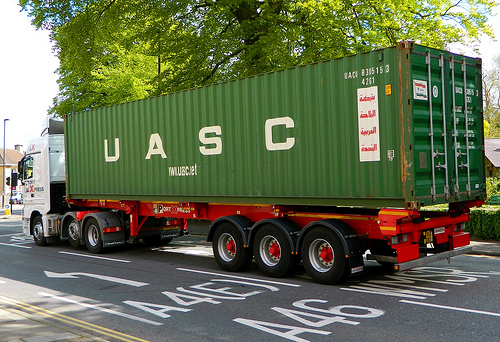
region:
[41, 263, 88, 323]
There is a white arrow here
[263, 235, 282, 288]
There is a black tire here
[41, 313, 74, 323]
There is yellow line here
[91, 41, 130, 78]
There are green trees here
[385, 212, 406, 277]
There are red areas here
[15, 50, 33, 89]
There is a white sky here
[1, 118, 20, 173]
There is a tall lamp post here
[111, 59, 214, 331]
Jackson Mingus took this photo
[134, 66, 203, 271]
This photo has a great deal of detail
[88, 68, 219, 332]
This photo is actually quite lovely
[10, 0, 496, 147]
bright blue sky through and beside tree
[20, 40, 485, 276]
white cab in front of large green container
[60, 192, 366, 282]
black wheels on side of truck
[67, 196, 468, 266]
red supporting platform on truck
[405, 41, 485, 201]
metal bars over ridged back wall of truck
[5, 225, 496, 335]
street of gray pavement with lines and information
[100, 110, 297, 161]
four white capital letters on truck side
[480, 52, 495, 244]
house in back of hedges behind truck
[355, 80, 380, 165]
white sign with word repeated four times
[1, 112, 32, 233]
lamppost by cab in front of building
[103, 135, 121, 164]
Letter on the side of a truck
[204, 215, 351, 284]
Three wheels on a truck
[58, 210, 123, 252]
Two wheels on a truck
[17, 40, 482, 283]
A truck driving on the road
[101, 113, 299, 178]
Letters on the side of a truck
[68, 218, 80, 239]
Industrial rim on a wheel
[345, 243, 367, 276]
A black mudflap on a truck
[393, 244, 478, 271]
Rear bumper of a truck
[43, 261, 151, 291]
Arrow painted on the street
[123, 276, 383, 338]
Letters and numbers on the road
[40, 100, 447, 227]
green and white truck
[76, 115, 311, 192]
white name on truck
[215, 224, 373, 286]
black and red tires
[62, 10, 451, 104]
green trees behind truck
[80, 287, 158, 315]
road is dark grey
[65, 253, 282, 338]
white lines on road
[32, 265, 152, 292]
white arrow on road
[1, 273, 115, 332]
yellow lines on road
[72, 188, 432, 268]
red bed on truck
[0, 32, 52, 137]
white and grey sky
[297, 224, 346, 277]
a large black truck tire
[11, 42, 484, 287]
a large green and white truck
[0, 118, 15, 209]
a tall lamp pole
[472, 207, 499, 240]
part of a green bush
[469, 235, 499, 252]
part of a sidewalk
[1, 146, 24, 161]
a roof of a building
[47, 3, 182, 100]
a large green tree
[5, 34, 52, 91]
part of a white sky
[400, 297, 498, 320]
a long white line